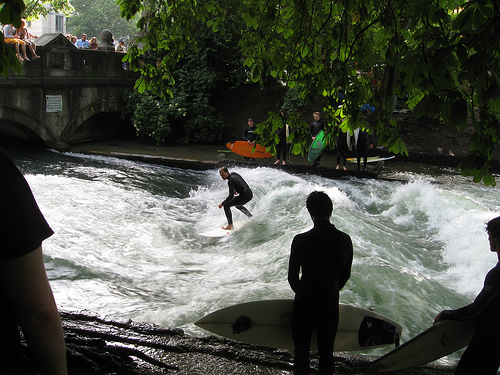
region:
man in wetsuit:
[215, 165, 253, 234]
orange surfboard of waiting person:
[222, 135, 280, 162]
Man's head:
[216, 163, 230, 180]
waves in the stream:
[375, 176, 482, 298]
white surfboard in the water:
[194, 220, 246, 241]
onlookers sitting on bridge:
[2, 13, 40, 67]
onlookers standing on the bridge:
[72, 31, 102, 49]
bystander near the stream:
[286, 188, 346, 373]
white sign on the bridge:
[41, 90, 66, 116]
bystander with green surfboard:
[300, 106, 331, 171]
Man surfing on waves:
[198, 165, 255, 238]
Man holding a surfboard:
[192, 190, 402, 374]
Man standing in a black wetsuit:
[285, 190, 354, 374]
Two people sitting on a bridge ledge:
[0, 17, 42, 64]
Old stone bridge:
[1, 33, 154, 150]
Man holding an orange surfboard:
[223, 115, 273, 167]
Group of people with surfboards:
[225, 105, 394, 172]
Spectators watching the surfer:
[64, 31, 141, 55]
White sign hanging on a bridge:
[44, 94, 63, 114]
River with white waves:
[3, 147, 498, 364]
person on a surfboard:
[194, 158, 265, 241]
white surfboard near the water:
[190, 297, 412, 352]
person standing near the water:
[272, 191, 362, 371]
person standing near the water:
[268, 102, 297, 171]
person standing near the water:
[238, 115, 260, 166]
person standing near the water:
[304, 105, 332, 166]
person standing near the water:
[330, 130, 349, 172]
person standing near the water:
[351, 117, 376, 177]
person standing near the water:
[0, 118, 71, 374]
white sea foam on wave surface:
[75, 194, 146, 256]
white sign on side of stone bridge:
[41, 88, 68, 118]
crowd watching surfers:
[0, 18, 137, 58]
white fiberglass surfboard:
[177, 295, 412, 357]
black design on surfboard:
[212, 308, 262, 342]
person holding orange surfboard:
[221, 114, 269, 159]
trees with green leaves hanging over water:
[166, 3, 498, 69]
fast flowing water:
[54, 146, 185, 319]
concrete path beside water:
[80, 128, 212, 162]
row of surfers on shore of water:
[200, 88, 411, 180]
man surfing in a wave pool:
[203, 165, 255, 243]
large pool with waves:
[16, 140, 499, 351]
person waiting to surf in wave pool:
[196, 191, 404, 371]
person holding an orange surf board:
[226, 116, 274, 159]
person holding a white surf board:
[199, 192, 406, 362]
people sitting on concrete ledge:
[3, 17, 45, 63]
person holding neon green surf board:
[302, 110, 335, 171]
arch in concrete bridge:
[59, 98, 151, 147]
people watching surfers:
[1, 18, 41, 68]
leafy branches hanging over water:
[108, 3, 497, 170]